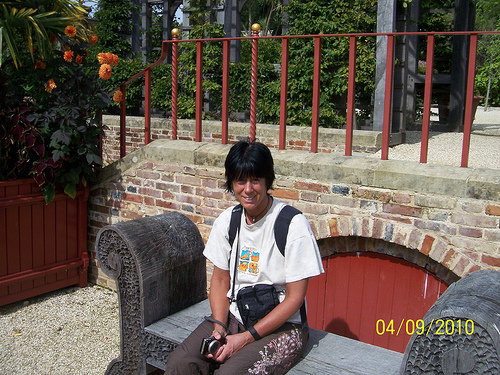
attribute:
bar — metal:
[274, 36, 291, 160]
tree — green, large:
[257, 5, 377, 127]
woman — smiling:
[212, 150, 329, 342]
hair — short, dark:
[225, 141, 275, 192]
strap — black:
[261, 190, 313, 277]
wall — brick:
[334, 173, 472, 228]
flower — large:
[0, 4, 117, 214]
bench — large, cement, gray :
[82, 202, 495, 374]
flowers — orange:
[33, 17, 124, 119]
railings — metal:
[222, 17, 449, 169]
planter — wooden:
[1, 175, 88, 305]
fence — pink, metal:
[98, 30, 492, 180]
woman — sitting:
[159, 132, 359, 372]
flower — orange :
[91, 65, 113, 86]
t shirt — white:
[198, 202, 325, 325]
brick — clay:
[304, 151, 366, 188]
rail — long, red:
[112, 27, 494, 162]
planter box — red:
[0, 188, 93, 309]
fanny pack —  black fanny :
[233, 276, 280, 334]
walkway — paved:
[418, 103, 470, 182]